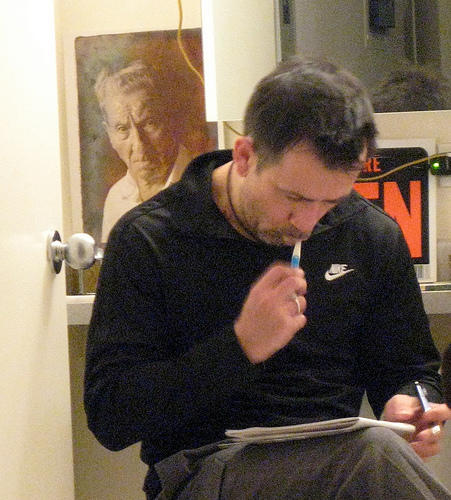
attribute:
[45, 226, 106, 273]
door handle — silver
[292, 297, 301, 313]
ring — silver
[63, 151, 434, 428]
pullover — black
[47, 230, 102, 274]
doorknob — silver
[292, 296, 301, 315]
wedding band — gold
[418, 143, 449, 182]
light — green, illuminated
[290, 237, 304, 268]
toothbrush — white and blue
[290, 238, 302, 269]
toothbrush — blue and white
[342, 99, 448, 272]
sign. — orange, black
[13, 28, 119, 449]
door — pink, open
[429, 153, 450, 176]
box — black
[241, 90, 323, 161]
hair — brown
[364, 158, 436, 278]
lettering — orange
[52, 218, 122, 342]
knob — silver and metal